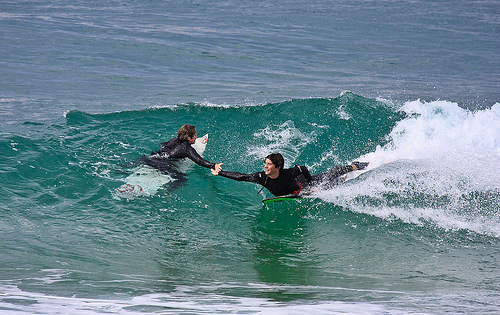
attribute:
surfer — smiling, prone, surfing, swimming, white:
[215, 154, 367, 196]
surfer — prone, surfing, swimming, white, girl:
[120, 125, 223, 200]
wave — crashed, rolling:
[5, 92, 495, 222]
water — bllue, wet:
[1, 2, 497, 311]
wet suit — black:
[128, 138, 214, 190]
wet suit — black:
[221, 170, 356, 196]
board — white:
[116, 134, 208, 201]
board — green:
[263, 196, 305, 206]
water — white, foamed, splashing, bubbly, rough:
[395, 101, 499, 229]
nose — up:
[195, 131, 209, 154]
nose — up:
[262, 198, 276, 205]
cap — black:
[267, 153, 284, 172]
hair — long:
[179, 124, 197, 141]